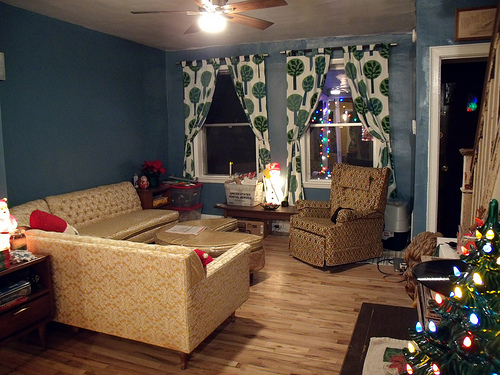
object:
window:
[197, 70, 253, 174]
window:
[306, 66, 375, 178]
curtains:
[338, 42, 393, 208]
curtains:
[285, 48, 333, 207]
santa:
[0, 193, 16, 267]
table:
[1, 256, 54, 352]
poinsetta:
[151, 160, 166, 185]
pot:
[149, 178, 159, 186]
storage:
[170, 181, 200, 206]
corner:
[161, 104, 175, 161]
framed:
[454, 7, 495, 42]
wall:
[415, 14, 451, 45]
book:
[0, 282, 33, 306]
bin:
[223, 183, 261, 208]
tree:
[387, 201, 499, 375]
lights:
[455, 287, 463, 299]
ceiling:
[86, 3, 119, 28]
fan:
[129, 0, 289, 36]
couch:
[7, 226, 253, 369]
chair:
[284, 164, 386, 272]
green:
[288, 59, 304, 71]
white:
[297, 73, 305, 81]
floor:
[272, 334, 316, 369]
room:
[4, 1, 498, 337]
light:
[199, 15, 228, 35]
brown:
[246, 3, 269, 9]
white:
[440, 45, 482, 55]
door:
[424, 43, 492, 237]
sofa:
[2, 180, 178, 263]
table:
[214, 201, 295, 217]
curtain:
[220, 56, 269, 184]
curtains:
[180, 58, 224, 183]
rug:
[338, 301, 418, 374]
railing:
[475, 156, 496, 194]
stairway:
[480, 94, 498, 139]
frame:
[421, 49, 440, 238]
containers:
[171, 179, 202, 207]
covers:
[171, 183, 202, 189]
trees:
[237, 66, 253, 96]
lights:
[317, 151, 321, 158]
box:
[243, 222, 265, 239]